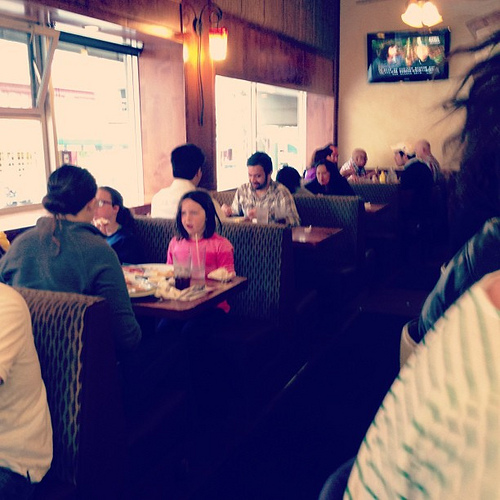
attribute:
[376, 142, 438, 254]
man — white 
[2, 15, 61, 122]
window — open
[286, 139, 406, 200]
family — eating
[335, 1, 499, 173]
wall — yellow 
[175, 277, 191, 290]
liquid — dark 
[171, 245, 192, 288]
glass — tall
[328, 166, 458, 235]
booth — black 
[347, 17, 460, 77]
television — small